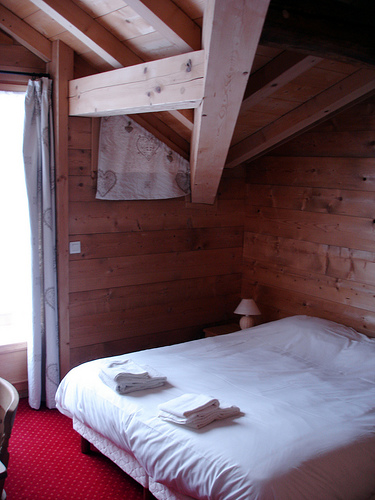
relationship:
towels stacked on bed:
[100, 362, 166, 393] [55, 314, 374, 499]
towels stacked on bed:
[158, 392, 241, 430] [55, 314, 374, 499]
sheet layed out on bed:
[55, 314, 374, 499] [55, 314, 374, 499]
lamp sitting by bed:
[233, 298, 260, 331] [55, 314, 374, 499]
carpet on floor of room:
[3, 397, 153, 499] [0, 1, 373, 499]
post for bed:
[80, 436, 90, 455] [55, 314, 374, 499]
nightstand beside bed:
[204, 322, 243, 338] [55, 314, 374, 499]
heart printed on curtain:
[96, 170, 117, 199] [95, 114, 193, 201]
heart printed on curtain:
[136, 135, 160, 159] [95, 114, 193, 201]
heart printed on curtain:
[175, 171, 191, 193] [95, 114, 193, 201]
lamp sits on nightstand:
[233, 298, 260, 331] [204, 322, 243, 338]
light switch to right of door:
[70, 240, 80, 256] [0, 72, 59, 403]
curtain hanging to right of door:
[23, 78, 58, 413] [0, 72, 59, 403]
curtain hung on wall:
[95, 114, 193, 201] [67, 115, 244, 374]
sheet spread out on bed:
[55, 314, 374, 499] [55, 314, 374, 499]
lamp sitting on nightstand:
[233, 298, 260, 331] [204, 322, 243, 338]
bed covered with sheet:
[55, 314, 374, 499] [55, 314, 374, 499]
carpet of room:
[3, 397, 153, 499] [0, 1, 373, 499]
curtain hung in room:
[95, 114, 193, 201] [0, 1, 373, 499]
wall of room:
[67, 115, 244, 374] [0, 1, 373, 499]